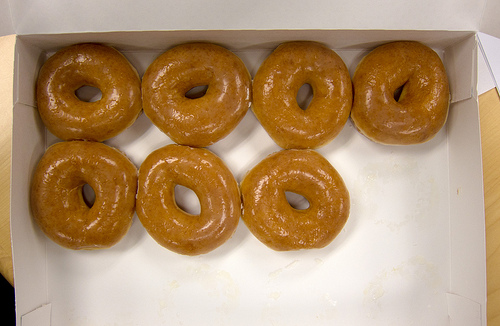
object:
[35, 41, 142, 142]
doughnut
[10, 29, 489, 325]
box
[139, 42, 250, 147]
doughnut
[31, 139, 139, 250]
doughnut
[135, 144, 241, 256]
doughnut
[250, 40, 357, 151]
doughnut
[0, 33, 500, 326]
table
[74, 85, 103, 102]
hole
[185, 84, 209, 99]
hole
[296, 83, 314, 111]
hole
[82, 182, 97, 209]
hole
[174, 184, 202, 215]
hole